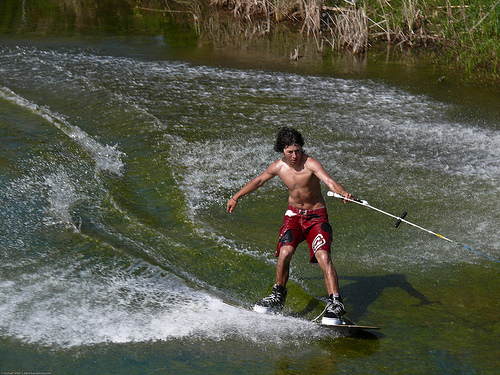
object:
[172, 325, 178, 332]
foam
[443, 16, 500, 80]
grass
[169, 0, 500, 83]
shoreline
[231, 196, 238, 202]
band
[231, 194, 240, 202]
wrist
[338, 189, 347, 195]
wrist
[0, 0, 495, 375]
water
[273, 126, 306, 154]
hair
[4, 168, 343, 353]
waves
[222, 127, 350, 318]
man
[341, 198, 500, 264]
line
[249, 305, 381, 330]
board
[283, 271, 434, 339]
shadow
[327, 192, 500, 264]
rope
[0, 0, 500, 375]
river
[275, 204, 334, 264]
shorts